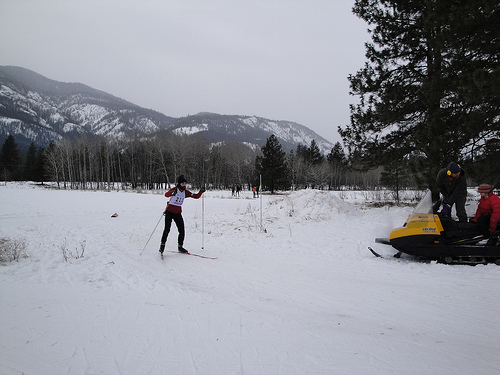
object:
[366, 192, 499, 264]
snowmobile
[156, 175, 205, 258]
person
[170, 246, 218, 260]
skis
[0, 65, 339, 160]
mountain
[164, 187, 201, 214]
red shirt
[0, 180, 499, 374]
snow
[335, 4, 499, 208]
tree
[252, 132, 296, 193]
tree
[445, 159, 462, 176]
earmuffs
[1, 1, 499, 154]
sky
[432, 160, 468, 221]
person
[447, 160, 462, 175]
yellow earmuffs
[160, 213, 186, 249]
pants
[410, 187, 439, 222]
glass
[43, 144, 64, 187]
tree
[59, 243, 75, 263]
branch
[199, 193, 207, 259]
ski pole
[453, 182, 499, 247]
person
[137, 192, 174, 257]
ski pole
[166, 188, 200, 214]
sweater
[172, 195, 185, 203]
number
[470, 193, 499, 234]
red coat